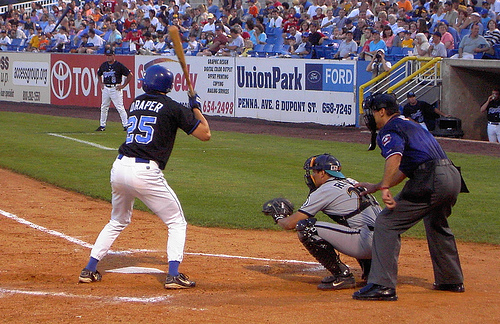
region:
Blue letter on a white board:
[232, 58, 246, 90]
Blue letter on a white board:
[243, 65, 252, 90]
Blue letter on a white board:
[248, 59, 260, 90]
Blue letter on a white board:
[256, 65, 263, 89]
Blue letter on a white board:
[264, 66, 266, 88]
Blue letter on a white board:
[271, 61, 283, 91]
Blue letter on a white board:
[278, 69, 289, 91]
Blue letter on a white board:
[286, 68, 297, 93]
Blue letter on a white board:
[289, 61, 304, 94]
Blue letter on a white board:
[235, 91, 352, 123]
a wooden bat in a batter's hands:
[165, 22, 197, 99]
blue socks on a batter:
[165, 255, 176, 275]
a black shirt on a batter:
[120, 90, 196, 161]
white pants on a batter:
[90, 152, 192, 262]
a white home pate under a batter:
[103, 257, 165, 280]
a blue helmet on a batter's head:
[140, 62, 177, 92]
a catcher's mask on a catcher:
[299, 152, 333, 195]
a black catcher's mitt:
[257, 196, 297, 223]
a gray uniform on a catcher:
[294, 176, 384, 263]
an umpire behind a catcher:
[346, 86, 470, 300]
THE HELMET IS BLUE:
[146, 65, 172, 95]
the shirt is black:
[123, 92, 203, 163]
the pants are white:
[107, 162, 198, 262]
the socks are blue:
[85, 254, 186, 272]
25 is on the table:
[126, 112, 159, 146]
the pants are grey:
[368, 168, 469, 288]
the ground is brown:
[218, 284, 273, 322]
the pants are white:
[93, 88, 128, 123]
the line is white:
[216, 245, 270, 265]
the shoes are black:
[351, 279, 403, 306]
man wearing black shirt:
[80, 53, 218, 298]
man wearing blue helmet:
[63, 40, 220, 296]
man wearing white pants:
[59, 25, 199, 301]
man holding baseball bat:
[72, 13, 209, 308]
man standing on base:
[87, 41, 130, 127]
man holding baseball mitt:
[255, 137, 364, 294]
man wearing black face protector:
[349, 78, 480, 300]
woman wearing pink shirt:
[434, 19, 457, 46]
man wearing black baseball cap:
[400, 86, 441, 127]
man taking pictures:
[365, 48, 402, 90]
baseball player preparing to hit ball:
[72, 20, 216, 289]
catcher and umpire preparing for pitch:
[256, 83, 475, 296]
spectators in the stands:
[216, 0, 360, 57]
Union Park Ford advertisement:
[236, 56, 358, 124]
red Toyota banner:
[48, 51, 133, 106]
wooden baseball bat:
[163, 19, 197, 96]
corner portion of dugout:
[438, 55, 498, 148]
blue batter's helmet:
[132, 63, 175, 93]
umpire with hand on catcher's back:
[356, 85, 476, 301]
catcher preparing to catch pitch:
[261, 147, 372, 289]